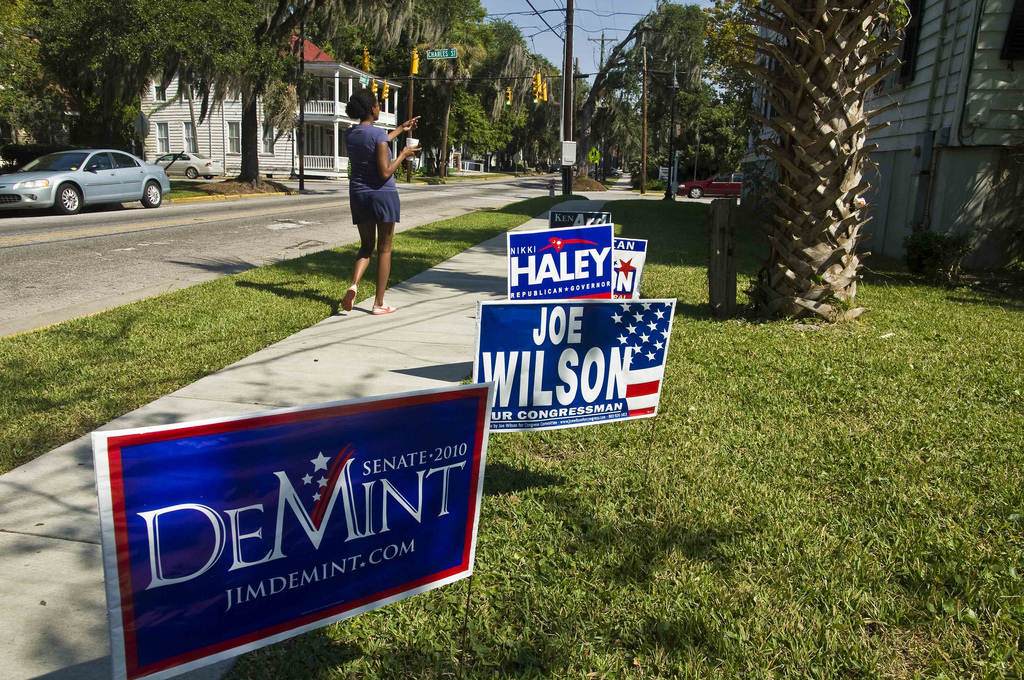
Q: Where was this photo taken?
A: Outside in a residential area.